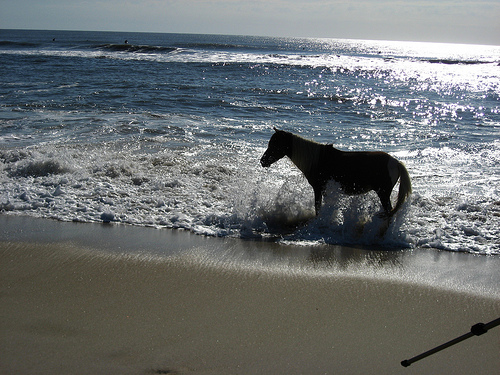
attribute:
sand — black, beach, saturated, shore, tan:
[2, 217, 499, 374]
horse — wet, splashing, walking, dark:
[260, 123, 413, 240]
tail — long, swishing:
[391, 161, 413, 223]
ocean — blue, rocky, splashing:
[3, 27, 500, 261]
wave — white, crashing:
[2, 47, 387, 76]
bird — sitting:
[125, 38, 128, 44]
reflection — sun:
[308, 34, 489, 62]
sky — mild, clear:
[1, 1, 500, 45]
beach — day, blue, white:
[0, 5, 499, 366]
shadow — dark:
[402, 318, 498, 368]